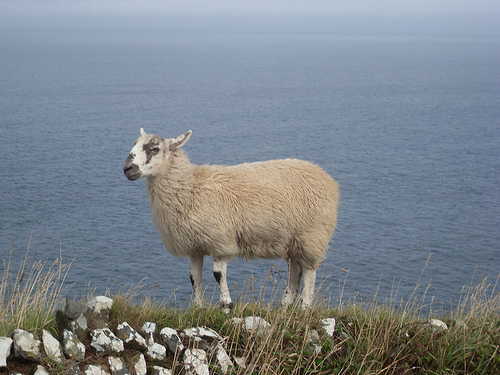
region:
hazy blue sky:
[2, 1, 499, 16]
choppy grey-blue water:
[5, 33, 492, 312]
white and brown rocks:
[2, 322, 214, 373]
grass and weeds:
[3, 240, 495, 374]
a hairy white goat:
[106, 117, 348, 329]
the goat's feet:
[182, 285, 322, 310]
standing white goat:
[114, 120, 345, 322]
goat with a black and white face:
[119, 123, 341, 301]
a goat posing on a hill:
[29, 119, 436, 356]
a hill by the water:
[5, 282, 490, 372]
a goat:
[112, 100, 382, 321]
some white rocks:
[11, 302, 265, 366]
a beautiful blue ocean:
[30, 18, 480, 112]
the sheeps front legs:
[174, 238, 255, 320]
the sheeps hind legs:
[278, 240, 335, 325]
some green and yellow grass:
[21, 252, 482, 363]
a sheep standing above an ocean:
[107, 80, 419, 301]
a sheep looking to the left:
[104, 114, 418, 319]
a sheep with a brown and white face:
[124, 111, 176, 183]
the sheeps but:
[268, 134, 365, 252]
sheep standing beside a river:
[122, 125, 340, 314]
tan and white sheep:
[122, 125, 339, 310]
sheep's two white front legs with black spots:
[180, 259, 235, 311]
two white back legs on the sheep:
[280, 268, 316, 309]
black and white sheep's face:
[124, 126, 194, 181]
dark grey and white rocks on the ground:
[0, 295, 335, 372]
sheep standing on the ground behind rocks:
[124, 124, 339, 374]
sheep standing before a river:
[4, 3, 498, 309]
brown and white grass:
[337, 333, 499, 372]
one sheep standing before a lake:
[0, 125, 499, 373]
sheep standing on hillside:
[125, 125, 342, 316]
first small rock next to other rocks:
[1, 341, 13, 371]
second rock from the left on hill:
[12, 329, 42, 365]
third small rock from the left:
[38, 329, 63, 365]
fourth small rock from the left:
[60, 328, 85, 364]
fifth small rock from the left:
[90, 325, 123, 357]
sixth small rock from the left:
[110, 316, 145, 351]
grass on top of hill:
[355, 285, 420, 365]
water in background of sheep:
[2, 142, 485, 288]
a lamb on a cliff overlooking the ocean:
[111, 108, 348, 323]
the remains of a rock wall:
[5, 289, 465, 373]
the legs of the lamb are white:
[186, 255, 316, 320]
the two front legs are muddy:
[183, 265, 230, 296]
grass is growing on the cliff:
[2, 262, 497, 372]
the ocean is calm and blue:
[7, 7, 495, 309]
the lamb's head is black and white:
[123, 122, 193, 183]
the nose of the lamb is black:
[121, 160, 139, 177]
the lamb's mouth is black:
[122, 169, 145, 184]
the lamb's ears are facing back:
[134, 123, 194, 157]